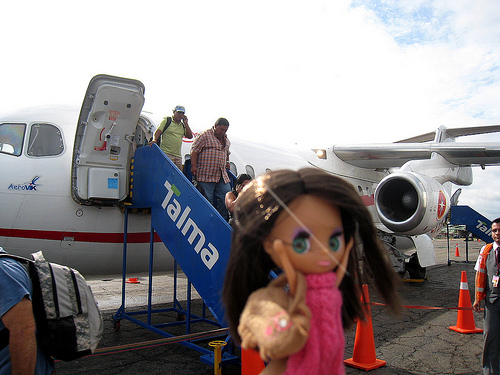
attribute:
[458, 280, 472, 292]
stripe — is white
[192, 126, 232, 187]
shirt — is plaid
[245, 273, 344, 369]
dress — is pink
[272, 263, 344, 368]
dress — is pink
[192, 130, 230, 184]
shirt — is checkered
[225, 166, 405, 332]
hair — is brown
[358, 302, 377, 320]
stripe — is white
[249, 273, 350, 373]
dress — pink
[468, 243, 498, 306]
vest — orange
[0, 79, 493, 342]
plane — is white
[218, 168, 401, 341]
hair — black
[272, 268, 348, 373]
clothes — pink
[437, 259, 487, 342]
orange cone — is orange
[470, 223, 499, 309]
orange vest — is orange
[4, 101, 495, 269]
white airplane — is white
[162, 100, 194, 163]
man talking — is talking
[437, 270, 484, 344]
orange white cone — is orange, is white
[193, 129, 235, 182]
checkered shirt — is checkered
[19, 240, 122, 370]
black backpack — is gray, is black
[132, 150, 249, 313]
word that says talma — is white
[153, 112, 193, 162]
green shirt — is green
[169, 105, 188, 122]
white hat — is white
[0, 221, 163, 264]
red stripe — is red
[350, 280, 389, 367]
orange traffic cone — is orange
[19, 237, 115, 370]
grey backpack — black, white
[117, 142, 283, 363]
airplane ladder — blue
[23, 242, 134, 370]
white backpack — Black, gray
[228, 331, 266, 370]
traffic cone — orange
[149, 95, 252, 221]
passengers departing — small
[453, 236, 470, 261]
safety cone behind — orange